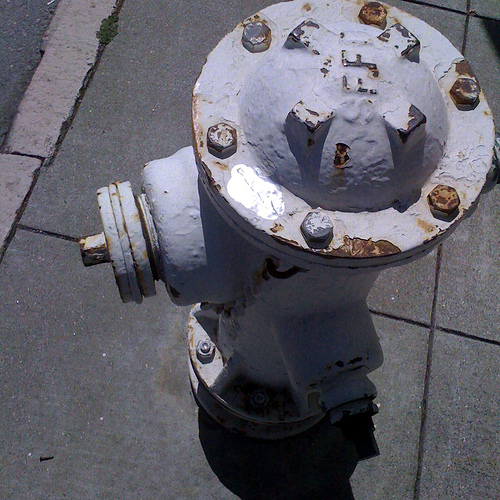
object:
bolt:
[449, 77, 482, 109]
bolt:
[355, 2, 387, 29]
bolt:
[299, 211, 331, 242]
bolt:
[205, 122, 237, 157]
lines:
[432, 322, 499, 347]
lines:
[17, 221, 80, 244]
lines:
[408, 0, 466, 16]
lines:
[1, 149, 44, 160]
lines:
[0, 223, 18, 262]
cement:
[414, 327, 499, 498]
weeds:
[95, 10, 119, 43]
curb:
[0, 0, 121, 255]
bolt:
[426, 183, 461, 216]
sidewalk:
[0, 0, 499, 500]